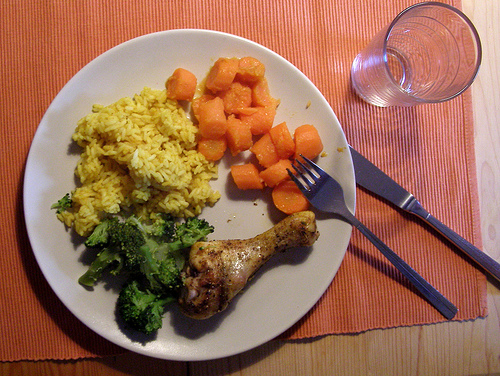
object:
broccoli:
[75, 214, 148, 289]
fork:
[282, 149, 463, 319]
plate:
[21, 26, 358, 364]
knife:
[347, 143, 500, 284]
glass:
[347, 0, 485, 110]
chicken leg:
[176, 209, 319, 321]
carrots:
[196, 94, 230, 140]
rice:
[55, 86, 222, 239]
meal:
[49, 54, 325, 336]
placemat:
[0, 0, 500, 376]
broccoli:
[50, 192, 74, 214]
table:
[0, 0, 500, 376]